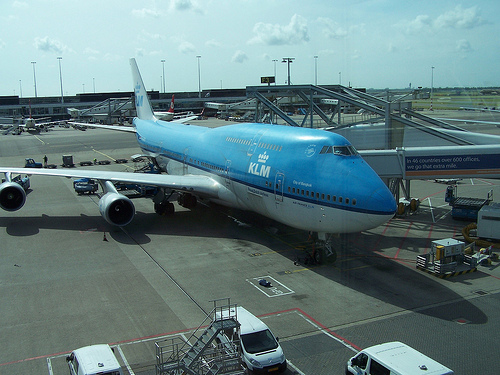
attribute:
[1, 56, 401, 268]
airplane — blue, white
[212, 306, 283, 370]
van — white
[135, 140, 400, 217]
stripe — blue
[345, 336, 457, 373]
van — white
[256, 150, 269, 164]
crown — white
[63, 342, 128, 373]
van — white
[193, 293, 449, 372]
vans — white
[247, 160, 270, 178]
klm — white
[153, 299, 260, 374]
platform — metal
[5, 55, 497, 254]
plane — blue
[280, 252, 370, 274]
line — yellow